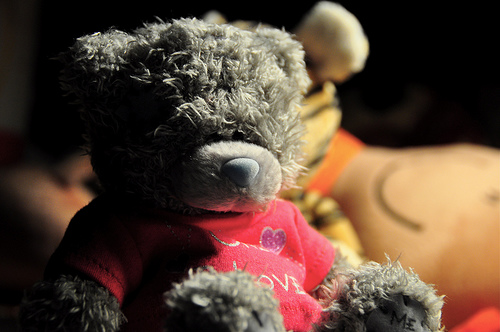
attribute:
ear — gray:
[259, 26, 313, 95]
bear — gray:
[18, 12, 449, 331]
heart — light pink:
[257, 225, 290, 257]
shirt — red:
[49, 183, 344, 330]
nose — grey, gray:
[218, 152, 261, 186]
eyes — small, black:
[257, 84, 276, 110]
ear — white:
[293, 1, 373, 84]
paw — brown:
[315, 254, 449, 331]